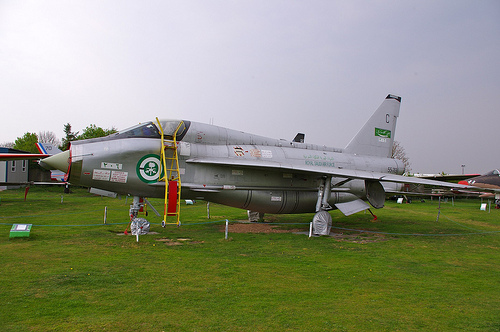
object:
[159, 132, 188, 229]
ladder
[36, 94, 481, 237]
airplane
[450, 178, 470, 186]
red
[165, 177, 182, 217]
panel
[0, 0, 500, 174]
sky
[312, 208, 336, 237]
landing gear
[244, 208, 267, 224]
landing gear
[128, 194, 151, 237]
landing gear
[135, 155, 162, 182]
patch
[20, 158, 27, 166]
window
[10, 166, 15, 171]
window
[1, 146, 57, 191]
house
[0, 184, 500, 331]
ground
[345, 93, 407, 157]
tail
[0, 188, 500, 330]
grass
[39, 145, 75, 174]
nose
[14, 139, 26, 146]
leaves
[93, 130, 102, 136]
leaves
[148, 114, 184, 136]
windshield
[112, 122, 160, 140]
window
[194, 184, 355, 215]
underbelly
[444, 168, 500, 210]
plane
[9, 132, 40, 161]
tree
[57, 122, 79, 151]
tree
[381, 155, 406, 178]
thrusts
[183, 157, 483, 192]
wing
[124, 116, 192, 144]
cockpit